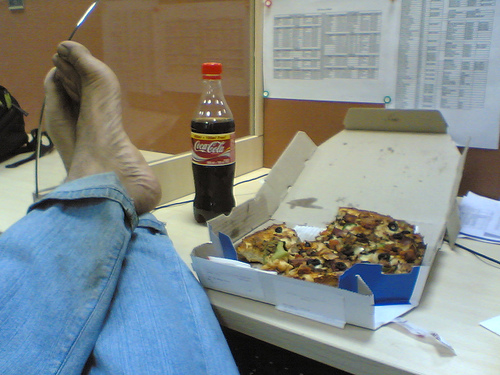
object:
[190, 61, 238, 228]
soda bottle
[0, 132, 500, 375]
desk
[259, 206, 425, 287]
pizza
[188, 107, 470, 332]
box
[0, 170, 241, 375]
jeans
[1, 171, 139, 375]
legs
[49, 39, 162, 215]
feet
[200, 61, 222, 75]
lid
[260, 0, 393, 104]
paper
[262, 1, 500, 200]
wall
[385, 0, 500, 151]
paper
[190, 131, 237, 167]
label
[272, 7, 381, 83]
print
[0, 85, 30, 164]
bag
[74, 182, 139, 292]
dirt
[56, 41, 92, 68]
toes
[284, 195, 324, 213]
stain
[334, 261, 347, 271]
olive